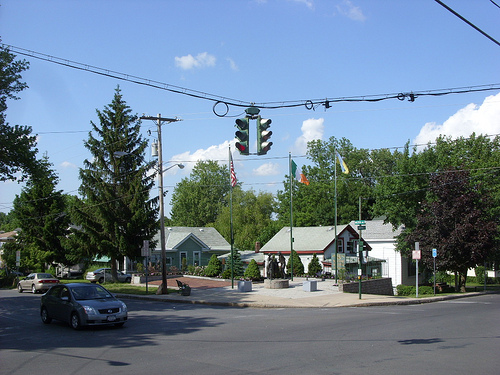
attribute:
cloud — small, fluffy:
[172, 50, 238, 76]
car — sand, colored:
[15, 270, 65, 295]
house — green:
[135, 222, 262, 283]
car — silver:
[39, 279, 146, 337]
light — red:
[219, 141, 244, 216]